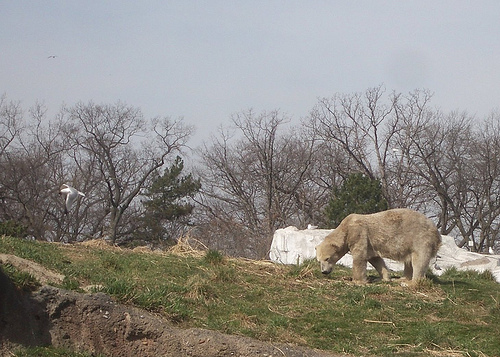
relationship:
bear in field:
[330, 207, 452, 282] [137, 257, 212, 291]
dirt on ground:
[118, 327, 143, 339] [211, 330, 226, 345]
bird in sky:
[58, 185, 86, 206] [127, 4, 250, 57]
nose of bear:
[321, 269, 333, 278] [330, 207, 452, 282]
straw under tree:
[174, 244, 200, 257] [125, 138, 149, 243]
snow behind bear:
[457, 264, 478, 275] [330, 207, 452, 282]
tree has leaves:
[125, 138, 149, 243] [177, 174, 194, 188]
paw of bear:
[350, 276, 367, 286] [330, 207, 452, 282]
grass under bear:
[107, 265, 232, 292] [330, 207, 452, 282]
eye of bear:
[323, 253, 331, 263] [330, 207, 452, 282]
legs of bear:
[344, 256, 401, 282] [330, 207, 452, 282]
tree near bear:
[125, 138, 149, 243] [330, 207, 452, 282]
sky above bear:
[127, 4, 250, 57] [330, 207, 452, 282]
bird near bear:
[58, 185, 86, 206] [330, 207, 452, 282]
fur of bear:
[368, 217, 387, 223] [330, 207, 452, 282]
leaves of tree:
[177, 174, 194, 188] [125, 138, 149, 243]